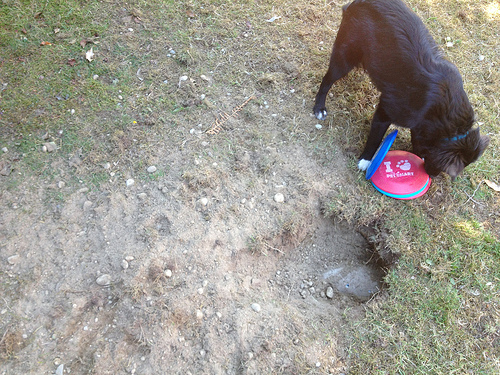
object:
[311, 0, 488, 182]
dog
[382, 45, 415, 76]
black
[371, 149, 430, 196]
kits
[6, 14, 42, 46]
grass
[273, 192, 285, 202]
stone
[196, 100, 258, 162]
ground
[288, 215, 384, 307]
hole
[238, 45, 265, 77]
soil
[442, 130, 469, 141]
collar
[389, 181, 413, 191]
red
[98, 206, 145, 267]
dirt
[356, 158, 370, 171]
feet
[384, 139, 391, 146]
blue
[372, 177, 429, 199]
frisbees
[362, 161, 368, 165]
white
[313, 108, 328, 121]
paw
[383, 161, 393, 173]
i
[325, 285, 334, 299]
rock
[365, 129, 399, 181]
frisbee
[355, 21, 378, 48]
fur